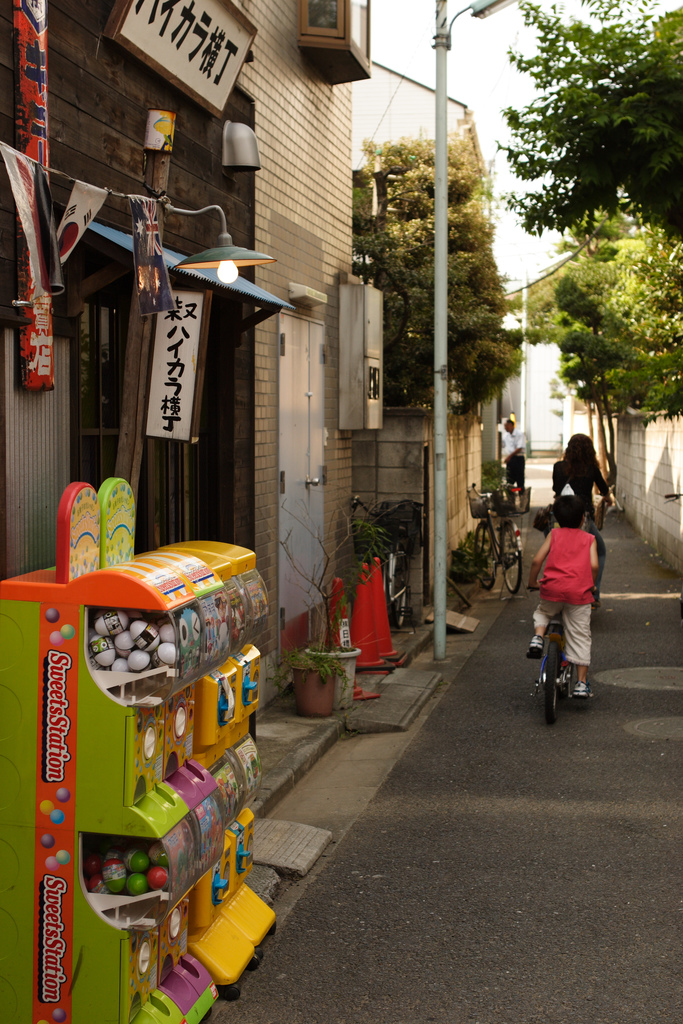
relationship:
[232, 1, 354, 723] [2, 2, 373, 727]
wall supporting building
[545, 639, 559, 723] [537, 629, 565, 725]
tire belonging to tire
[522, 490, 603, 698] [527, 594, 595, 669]
boy wearing shorts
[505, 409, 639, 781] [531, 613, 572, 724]
people on a bicycle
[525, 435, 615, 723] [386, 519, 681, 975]
people in an ally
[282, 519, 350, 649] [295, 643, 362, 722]
plant on pot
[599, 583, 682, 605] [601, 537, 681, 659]
light on ground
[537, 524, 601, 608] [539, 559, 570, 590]
shirt has wrinkles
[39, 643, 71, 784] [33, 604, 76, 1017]
writing on background